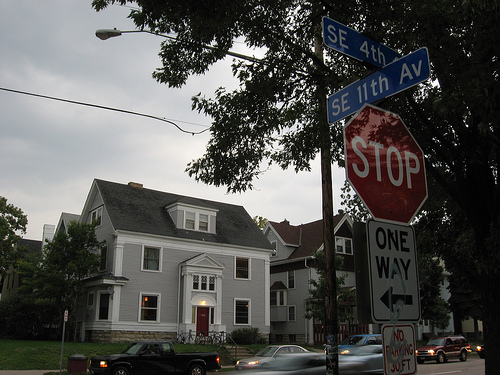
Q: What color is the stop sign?
A: Red.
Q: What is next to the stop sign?
A: Street signs.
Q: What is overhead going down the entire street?
A: Power lines.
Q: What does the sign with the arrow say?
A: One way.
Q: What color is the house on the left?
A: Gray.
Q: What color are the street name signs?
A: Blue.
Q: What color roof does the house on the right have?
A: Brown.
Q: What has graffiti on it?
A: Road signs.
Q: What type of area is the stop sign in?
A: Residential.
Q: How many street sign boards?
A: 2.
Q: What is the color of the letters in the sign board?
A: White.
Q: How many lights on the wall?
A: 1.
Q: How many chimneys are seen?
A: 1.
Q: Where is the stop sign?
A: At the corner.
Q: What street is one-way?
A: SE 4th.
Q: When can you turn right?
A: Never.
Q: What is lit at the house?
A: The front door light.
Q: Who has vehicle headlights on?
A: The drivers.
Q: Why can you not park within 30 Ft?
A: A no-parking zone.